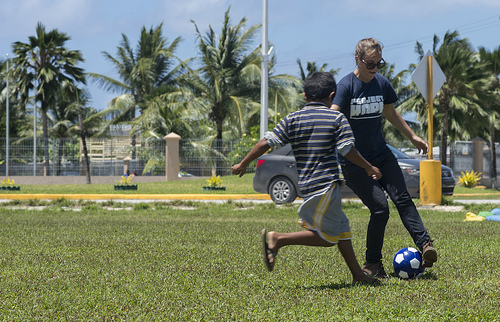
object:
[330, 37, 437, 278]
man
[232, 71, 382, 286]
boy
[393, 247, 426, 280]
ball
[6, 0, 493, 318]
soccer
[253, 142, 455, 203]
car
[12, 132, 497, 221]
lot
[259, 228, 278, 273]
sandals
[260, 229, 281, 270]
feet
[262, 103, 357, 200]
shirt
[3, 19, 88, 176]
trees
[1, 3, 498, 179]
background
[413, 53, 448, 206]
post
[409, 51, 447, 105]
sign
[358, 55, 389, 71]
sunglasses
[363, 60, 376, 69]
eyes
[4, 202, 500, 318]
field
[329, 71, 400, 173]
shirt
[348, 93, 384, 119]
writing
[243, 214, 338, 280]
air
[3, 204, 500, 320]
grass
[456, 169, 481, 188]
flowers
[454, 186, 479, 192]
pot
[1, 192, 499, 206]
curb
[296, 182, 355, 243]
shorts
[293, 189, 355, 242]
trim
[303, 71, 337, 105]
head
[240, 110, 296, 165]
arm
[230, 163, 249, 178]
hand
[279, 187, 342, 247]
leg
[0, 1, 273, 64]
sky